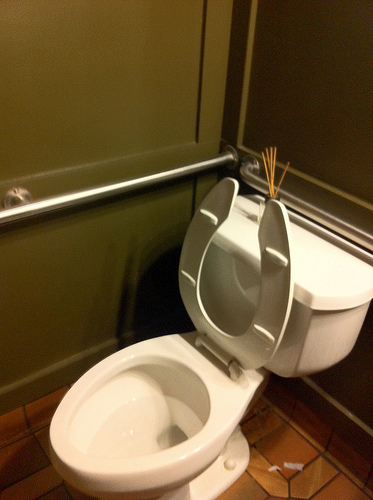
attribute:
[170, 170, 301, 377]
seat — white 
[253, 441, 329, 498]
floor — brown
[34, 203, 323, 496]
toulet — white 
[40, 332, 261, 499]
toilet bowl — white 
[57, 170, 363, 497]
toilet — white 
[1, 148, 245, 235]
rod — metal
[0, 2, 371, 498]
room — dark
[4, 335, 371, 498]
floor — brown 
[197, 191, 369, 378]
cistern — white 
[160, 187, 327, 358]
seat — open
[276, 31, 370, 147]
wall — green